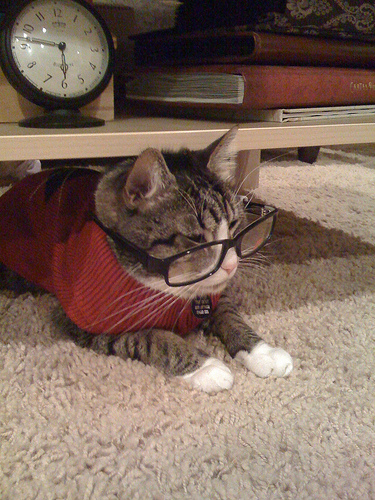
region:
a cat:
[97, 170, 214, 322]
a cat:
[135, 245, 185, 340]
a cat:
[105, 208, 206, 378]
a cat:
[116, 160, 279, 453]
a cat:
[80, 249, 217, 487]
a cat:
[142, 183, 227, 371]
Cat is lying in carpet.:
[31, 174, 291, 367]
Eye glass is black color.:
[97, 200, 290, 288]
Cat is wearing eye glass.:
[97, 177, 309, 315]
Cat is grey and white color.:
[60, 191, 293, 382]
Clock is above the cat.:
[8, 17, 122, 129]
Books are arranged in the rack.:
[174, 8, 337, 125]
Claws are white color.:
[185, 299, 287, 340]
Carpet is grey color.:
[66, 370, 199, 476]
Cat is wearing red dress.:
[37, 211, 136, 323]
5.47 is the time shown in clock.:
[16, 21, 124, 114]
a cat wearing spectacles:
[174, 191, 285, 289]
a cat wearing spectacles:
[144, 195, 313, 488]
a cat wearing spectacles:
[75, 212, 168, 370]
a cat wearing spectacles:
[128, 188, 243, 283]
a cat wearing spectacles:
[121, 236, 256, 459]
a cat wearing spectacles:
[119, 146, 271, 396]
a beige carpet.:
[120, 388, 316, 494]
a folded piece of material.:
[247, 0, 373, 42]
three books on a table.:
[128, 26, 368, 121]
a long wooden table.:
[0, 108, 371, 164]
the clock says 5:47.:
[0, 0, 124, 120]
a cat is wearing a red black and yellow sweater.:
[7, 163, 108, 320]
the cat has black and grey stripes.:
[25, 124, 277, 403]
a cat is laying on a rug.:
[0, 146, 310, 384]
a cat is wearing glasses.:
[98, 191, 291, 291]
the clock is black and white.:
[0, 1, 147, 129]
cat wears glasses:
[120, 152, 266, 305]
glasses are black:
[156, 225, 272, 297]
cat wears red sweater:
[4, 178, 200, 315]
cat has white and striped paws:
[73, 308, 268, 398]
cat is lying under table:
[71, 129, 239, 443]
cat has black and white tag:
[175, 291, 222, 323]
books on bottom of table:
[187, 11, 365, 144]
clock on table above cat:
[0, 14, 115, 122]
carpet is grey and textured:
[25, 260, 358, 465]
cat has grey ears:
[119, 152, 175, 213]